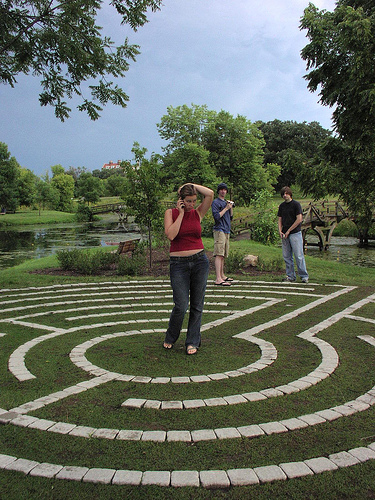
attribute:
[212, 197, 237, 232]
shirt — blue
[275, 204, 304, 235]
tshirt — black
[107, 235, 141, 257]
briddge — wooden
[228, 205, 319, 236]
briddge — arched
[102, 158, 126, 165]
roof — red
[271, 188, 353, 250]
structure — wooden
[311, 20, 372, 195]
tree — green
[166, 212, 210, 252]
top — red, maroon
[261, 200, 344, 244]
bench — wooden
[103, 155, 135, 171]
mansion — white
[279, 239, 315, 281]
jeans — blue